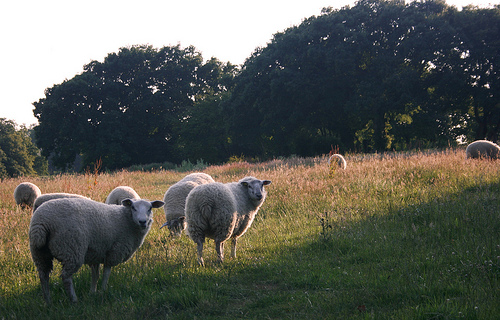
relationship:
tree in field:
[31, 41, 242, 167] [5, 147, 499, 320]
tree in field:
[176, 2, 495, 161] [5, 147, 499, 320]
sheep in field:
[11, 180, 43, 210] [5, 147, 499, 320]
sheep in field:
[33, 191, 84, 219] [5, 147, 499, 320]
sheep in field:
[29, 199, 166, 306] [5, 147, 499, 320]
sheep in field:
[104, 186, 141, 211] [5, 147, 499, 320]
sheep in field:
[158, 172, 214, 242] [5, 147, 499, 320]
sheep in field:
[183, 176, 273, 269] [5, 147, 499, 320]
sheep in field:
[327, 153, 346, 174] [5, 147, 499, 320]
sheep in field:
[464, 141, 500, 163] [5, 147, 499, 320]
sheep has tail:
[29, 199, 166, 306] [28, 221, 46, 249]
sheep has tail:
[183, 176, 273, 269] [199, 201, 213, 221]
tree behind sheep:
[31, 41, 242, 167] [104, 186, 141, 211]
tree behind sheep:
[176, 2, 495, 161] [327, 153, 346, 174]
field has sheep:
[5, 147, 499, 320] [11, 180, 43, 210]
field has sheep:
[5, 147, 499, 320] [33, 191, 84, 219]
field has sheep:
[5, 147, 499, 320] [29, 199, 166, 306]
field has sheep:
[5, 147, 499, 320] [104, 186, 141, 211]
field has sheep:
[5, 147, 499, 320] [158, 172, 214, 242]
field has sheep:
[5, 147, 499, 320] [183, 176, 273, 269]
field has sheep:
[5, 147, 499, 320] [327, 153, 346, 174]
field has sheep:
[5, 147, 499, 320] [464, 141, 500, 163]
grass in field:
[0, 154, 498, 319] [5, 147, 499, 320]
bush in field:
[120, 162, 174, 172] [5, 147, 499, 320]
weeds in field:
[175, 158, 207, 172] [5, 147, 499, 320]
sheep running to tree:
[183, 176, 273, 269] [176, 2, 495, 161]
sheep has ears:
[183, 176, 273, 269] [261, 179, 273, 186]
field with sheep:
[5, 147, 499, 320] [183, 176, 273, 269]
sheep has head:
[183, 176, 273, 269] [241, 176, 273, 208]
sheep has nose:
[183, 176, 273, 269] [257, 192, 264, 199]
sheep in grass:
[183, 176, 273, 269] [0, 154, 498, 319]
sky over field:
[1, 0, 497, 131] [5, 147, 499, 320]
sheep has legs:
[29, 199, 166, 306] [31, 252, 113, 301]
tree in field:
[1, 117, 47, 177] [5, 147, 499, 320]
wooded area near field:
[1, 0, 499, 175] [5, 147, 499, 320]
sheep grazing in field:
[183, 176, 273, 269] [5, 147, 499, 320]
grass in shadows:
[0, 154, 498, 319] [0, 181, 499, 319]